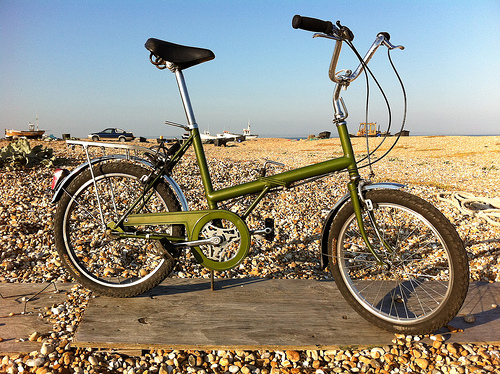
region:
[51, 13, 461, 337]
bike on a board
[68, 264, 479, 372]
board under the bike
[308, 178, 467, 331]
front tire on the bike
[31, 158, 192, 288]
rear tire on the bike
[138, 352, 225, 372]
rocks under the board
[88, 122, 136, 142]
vehicle in the distance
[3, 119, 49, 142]
boat in the distance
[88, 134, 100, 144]
front tire on the vehicle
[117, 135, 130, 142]
rear tire on the vehicle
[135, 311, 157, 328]
hole in the board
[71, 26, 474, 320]
a small green bike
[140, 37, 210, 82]
the seat of a bike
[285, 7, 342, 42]
the handle of a bike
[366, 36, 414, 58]
the brakes of a bike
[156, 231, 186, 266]
the pedals of a bike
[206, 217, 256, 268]
the gears of a bike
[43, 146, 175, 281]
the back wheel of a bike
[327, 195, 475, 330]
the front wheel of a bike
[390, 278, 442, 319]
the spokes of a bike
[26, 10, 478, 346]
Single green bicycle.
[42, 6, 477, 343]
Bicycle standing upright on a piece of wood board.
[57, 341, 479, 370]
Stones covering the ground.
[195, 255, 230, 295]
Metal kickstand holding the bike upright.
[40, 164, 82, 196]
Red reflective light on the tire.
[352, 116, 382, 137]
Large yellow piece of construction equipment.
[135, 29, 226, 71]
All black bicycle seat.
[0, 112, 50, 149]
Boat sitting on the shore.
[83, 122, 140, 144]
Dark colored truck with a light colored stripe on it.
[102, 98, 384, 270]
a green StingRay bicycle sits on a board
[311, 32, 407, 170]
the bicycle uses hand brakes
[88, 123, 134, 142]
a pickup truck is parked across the stones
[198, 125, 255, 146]
a two white boats are parked on the beach.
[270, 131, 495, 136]
a thin ribbon of water is on the horizon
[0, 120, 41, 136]
a gold and white boat in the background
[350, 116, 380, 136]
a yellow piece of heavy earth moving equipment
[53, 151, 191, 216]
the bike has silver fenders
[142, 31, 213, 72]
a black bike seat raised high for longer legs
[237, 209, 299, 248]
bike has a black pedal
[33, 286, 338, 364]
a wooden brown plank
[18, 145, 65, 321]
lots of rocks on ground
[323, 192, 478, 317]
writing on the tire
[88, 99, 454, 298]
the body is green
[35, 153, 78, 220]
a red stop light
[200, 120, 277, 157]
boats in the distance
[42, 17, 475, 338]
green bike sitting on sidewalk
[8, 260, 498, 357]
wooden board planks under bike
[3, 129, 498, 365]
pebble lined edge of beach front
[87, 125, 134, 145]
black car sitting on beach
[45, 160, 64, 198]
red tail light on bike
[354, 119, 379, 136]
yellow tractor sitting on beach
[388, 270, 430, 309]
silver spoke on tire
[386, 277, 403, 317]
silver spoke on tire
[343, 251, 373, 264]
silver spoke on tire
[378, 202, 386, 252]
silver spoke on tire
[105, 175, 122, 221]
silver spoke on tire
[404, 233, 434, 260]
silver spoke on tire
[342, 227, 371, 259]
silver spoke on tire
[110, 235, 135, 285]
silver spoke on tire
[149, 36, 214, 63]
black sit of the bike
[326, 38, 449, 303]
fornt part of the bike